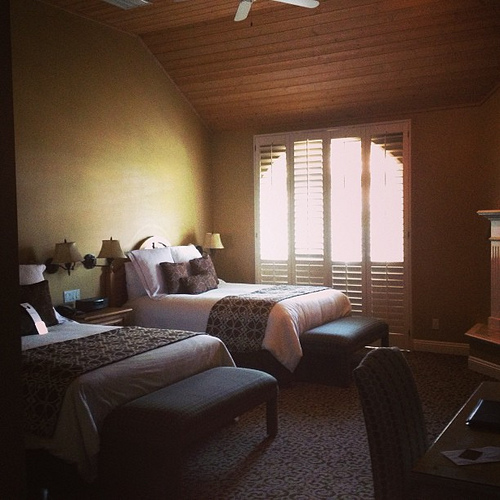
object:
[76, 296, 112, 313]
clock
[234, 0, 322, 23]
fan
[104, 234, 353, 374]
bed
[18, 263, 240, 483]
bed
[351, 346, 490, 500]
chair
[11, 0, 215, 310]
wall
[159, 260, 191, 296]
pillow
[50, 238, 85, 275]
lamp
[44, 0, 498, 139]
ceiling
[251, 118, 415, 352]
shade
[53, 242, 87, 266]
shade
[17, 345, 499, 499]
carpet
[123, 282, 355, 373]
sheet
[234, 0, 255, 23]
blade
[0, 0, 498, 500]
room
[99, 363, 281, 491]
bench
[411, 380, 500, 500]
desk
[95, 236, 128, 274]
lamp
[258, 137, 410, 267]
window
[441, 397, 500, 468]
objects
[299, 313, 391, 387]
bench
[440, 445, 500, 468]
paper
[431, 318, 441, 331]
outlet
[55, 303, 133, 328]
table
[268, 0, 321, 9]
blade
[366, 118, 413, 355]
panel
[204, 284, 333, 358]
blanket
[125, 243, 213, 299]
pillow